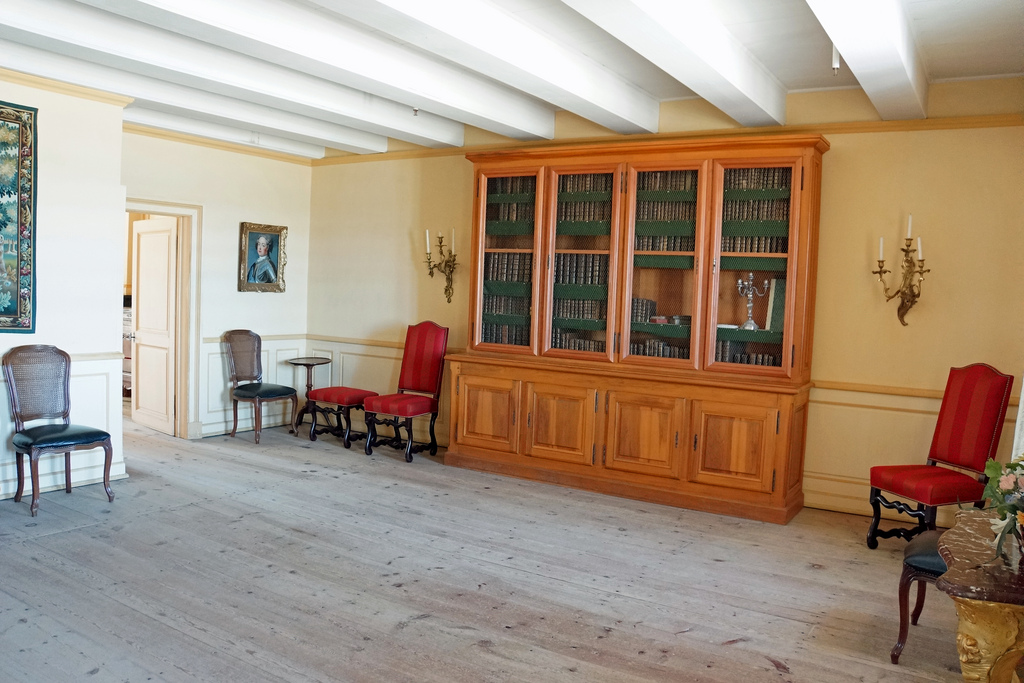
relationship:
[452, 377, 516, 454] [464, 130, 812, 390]
door on cabinet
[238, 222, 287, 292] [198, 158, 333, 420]
frame hanging on wall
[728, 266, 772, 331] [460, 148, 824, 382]
holder in book case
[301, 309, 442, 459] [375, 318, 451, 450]
stool next to chair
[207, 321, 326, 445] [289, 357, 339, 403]
chair next to table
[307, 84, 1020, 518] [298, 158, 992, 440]
wainscoating on wall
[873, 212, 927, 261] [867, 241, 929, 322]
candles in sconce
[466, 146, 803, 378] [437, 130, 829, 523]
doors on bookcase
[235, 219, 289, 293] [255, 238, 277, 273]
portrait of man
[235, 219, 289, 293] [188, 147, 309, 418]
portrait on wall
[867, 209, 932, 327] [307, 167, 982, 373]
candle holder on wall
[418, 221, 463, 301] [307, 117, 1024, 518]
candle holder on wainscoating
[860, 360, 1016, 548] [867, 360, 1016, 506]
chair with cushions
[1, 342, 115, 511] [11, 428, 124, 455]
chair with seat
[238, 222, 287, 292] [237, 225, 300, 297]
frame has frame